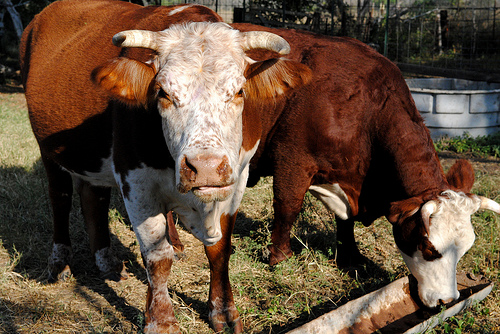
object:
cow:
[17, 2, 312, 334]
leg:
[267, 155, 318, 266]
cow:
[225, 23, 500, 309]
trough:
[278, 269, 496, 333]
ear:
[242, 57, 314, 110]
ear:
[90, 57, 155, 110]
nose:
[180, 153, 233, 183]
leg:
[120, 188, 175, 334]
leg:
[204, 206, 244, 333]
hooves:
[143, 308, 179, 334]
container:
[403, 77, 498, 141]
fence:
[232, 6, 499, 82]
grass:
[1, 90, 500, 334]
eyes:
[235, 88, 245, 98]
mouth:
[175, 179, 238, 203]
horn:
[421, 200, 437, 237]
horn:
[479, 196, 500, 214]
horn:
[238, 30, 291, 54]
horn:
[111, 29, 159, 53]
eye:
[156, 86, 171, 102]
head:
[386, 157, 499, 311]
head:
[91, 20, 312, 206]